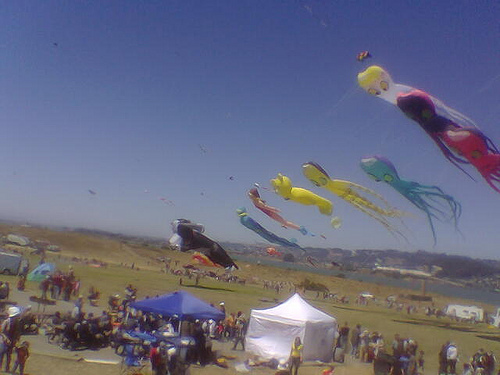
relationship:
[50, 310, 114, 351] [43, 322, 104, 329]
people sitting on a bench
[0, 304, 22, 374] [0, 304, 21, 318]
person has hat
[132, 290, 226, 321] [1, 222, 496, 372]
tent sitting in field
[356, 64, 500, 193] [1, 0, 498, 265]
kite against sky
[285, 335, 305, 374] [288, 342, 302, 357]
woman wearing a shirt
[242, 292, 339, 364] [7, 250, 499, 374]
tent in field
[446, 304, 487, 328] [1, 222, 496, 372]
camper in field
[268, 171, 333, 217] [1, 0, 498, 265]
kite in sky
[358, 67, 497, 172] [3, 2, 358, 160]
kite flying sky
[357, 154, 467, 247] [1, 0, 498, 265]
kite flying sky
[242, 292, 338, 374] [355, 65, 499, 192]
tent under kite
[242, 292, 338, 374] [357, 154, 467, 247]
tent under kite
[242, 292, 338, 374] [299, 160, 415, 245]
tent under kite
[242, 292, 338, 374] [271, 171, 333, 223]
tent under kite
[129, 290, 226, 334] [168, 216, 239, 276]
tent under dog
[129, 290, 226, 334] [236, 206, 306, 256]
tent under kite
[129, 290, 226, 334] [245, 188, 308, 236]
tent under kite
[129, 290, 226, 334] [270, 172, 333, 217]
tent under kite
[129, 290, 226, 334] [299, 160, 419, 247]
tent under kite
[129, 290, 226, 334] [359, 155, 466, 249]
tent under kite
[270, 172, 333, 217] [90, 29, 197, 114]
kite in sky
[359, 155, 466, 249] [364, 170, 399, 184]
kite with yellow eyes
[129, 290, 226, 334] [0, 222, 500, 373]
tent on ground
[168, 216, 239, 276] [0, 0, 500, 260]
dog in skies